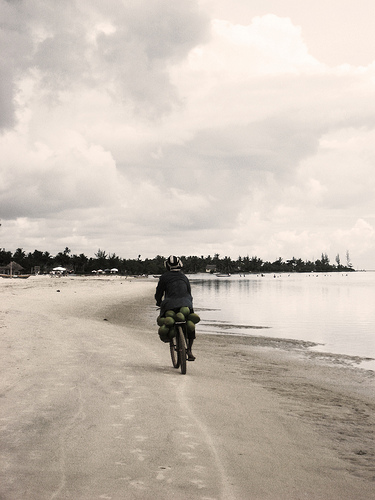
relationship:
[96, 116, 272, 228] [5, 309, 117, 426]
sky above sand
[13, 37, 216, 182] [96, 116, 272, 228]
clouds are in sky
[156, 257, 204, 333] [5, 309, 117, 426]
man rides on sand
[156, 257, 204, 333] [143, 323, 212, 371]
man rides bike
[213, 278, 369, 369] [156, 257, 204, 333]
water next to man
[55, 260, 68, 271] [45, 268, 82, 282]
roof on top of house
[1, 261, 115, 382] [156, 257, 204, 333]
beach next to man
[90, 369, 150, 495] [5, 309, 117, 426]
footprints along sand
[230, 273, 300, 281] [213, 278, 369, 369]
people playing in water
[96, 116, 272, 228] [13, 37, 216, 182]
sky has clouds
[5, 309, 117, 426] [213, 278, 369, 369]
sand next to water